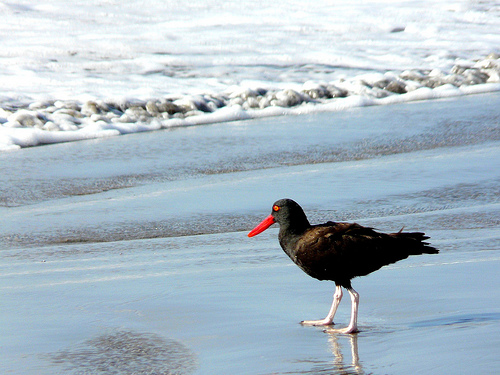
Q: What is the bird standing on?
A: Sand.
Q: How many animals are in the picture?
A: One.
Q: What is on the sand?
A: Waves.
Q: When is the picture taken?
A: Daytime.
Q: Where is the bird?
A: On the sand.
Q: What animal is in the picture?
A: Bird.